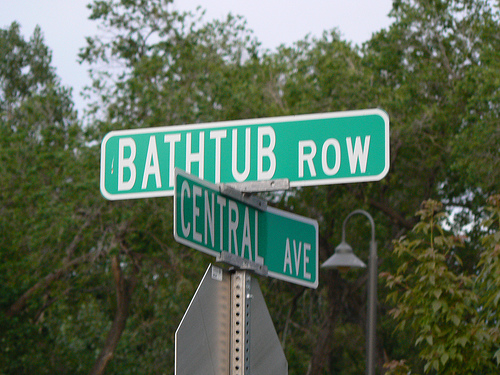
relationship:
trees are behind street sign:
[1, 0, 499, 374] [97, 108, 396, 293]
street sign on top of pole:
[97, 108, 396, 293] [226, 267, 254, 375]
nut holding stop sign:
[247, 292, 255, 300] [174, 261, 289, 374]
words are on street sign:
[117, 123, 371, 191] [97, 108, 396, 293]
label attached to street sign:
[212, 265, 224, 282] [97, 108, 396, 293]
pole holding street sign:
[226, 267, 254, 375] [97, 108, 396, 293]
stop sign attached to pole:
[174, 261, 289, 374] [226, 267, 254, 375]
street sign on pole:
[97, 108, 396, 293] [226, 267, 254, 375]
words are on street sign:
[179, 179, 312, 282] [97, 108, 396, 293]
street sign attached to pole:
[97, 108, 396, 293] [226, 267, 254, 375]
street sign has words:
[97, 108, 396, 293] [117, 123, 371, 191]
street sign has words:
[97, 108, 396, 293] [179, 179, 312, 282]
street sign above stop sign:
[97, 108, 396, 293] [174, 261, 289, 374]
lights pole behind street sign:
[320, 207, 380, 374] [97, 108, 396, 293]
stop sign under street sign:
[174, 261, 289, 374] [97, 108, 396, 293]